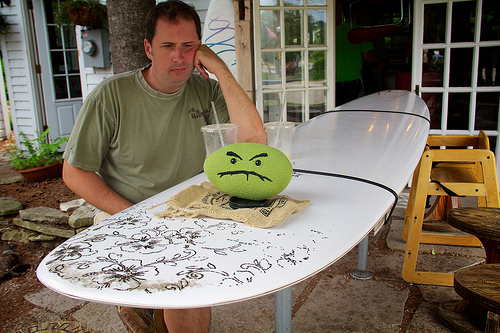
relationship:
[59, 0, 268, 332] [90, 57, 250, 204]
adult in shirt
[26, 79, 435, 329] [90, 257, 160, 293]
surfboard with flower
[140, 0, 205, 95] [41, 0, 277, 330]
head of adult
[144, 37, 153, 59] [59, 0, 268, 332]
ear of adult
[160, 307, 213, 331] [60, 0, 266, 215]
leg of adult male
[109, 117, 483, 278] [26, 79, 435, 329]
table made of surfboard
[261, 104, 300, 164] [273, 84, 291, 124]
cup with drinking straw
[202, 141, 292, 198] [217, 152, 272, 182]
nut with face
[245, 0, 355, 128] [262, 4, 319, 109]
door with glass panels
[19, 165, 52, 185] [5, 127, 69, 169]
planter with plant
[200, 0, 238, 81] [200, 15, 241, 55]
surfboard with design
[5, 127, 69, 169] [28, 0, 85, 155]
plant at doorway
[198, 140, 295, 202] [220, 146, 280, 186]
green oval with face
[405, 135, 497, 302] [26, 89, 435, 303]
chair behind surfboard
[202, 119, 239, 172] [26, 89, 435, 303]
cup on surfboard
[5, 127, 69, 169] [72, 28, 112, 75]
plant over meter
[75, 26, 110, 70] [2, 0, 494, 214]
meter on house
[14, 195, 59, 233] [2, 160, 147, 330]
stones on ground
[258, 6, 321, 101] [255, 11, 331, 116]
reflection in window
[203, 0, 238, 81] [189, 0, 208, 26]
surfboard against wall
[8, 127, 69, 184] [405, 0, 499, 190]
plant by door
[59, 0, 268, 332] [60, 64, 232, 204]
adult wearing shirt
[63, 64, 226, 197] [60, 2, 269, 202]
shirt of a male